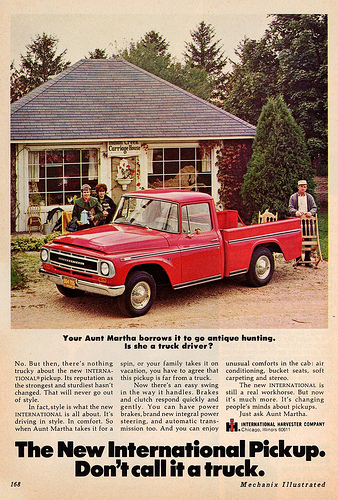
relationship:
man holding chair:
[288, 177, 319, 273] [295, 214, 325, 270]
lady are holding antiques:
[72, 183, 105, 233] [76, 202, 111, 227]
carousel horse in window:
[155, 166, 197, 191] [144, 144, 212, 198]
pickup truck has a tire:
[40, 185, 306, 317] [119, 269, 157, 320]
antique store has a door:
[9, 58, 262, 232] [110, 156, 137, 210]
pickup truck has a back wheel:
[40, 185, 306, 317] [247, 246, 274, 288]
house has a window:
[9, 58, 262, 232] [144, 144, 212, 198]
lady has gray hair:
[69, 180, 105, 233] [79, 179, 92, 193]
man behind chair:
[288, 177, 319, 273] [295, 214, 325, 270]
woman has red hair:
[93, 180, 118, 222] [94, 180, 109, 194]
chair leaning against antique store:
[27, 203, 44, 235] [9, 58, 262, 232]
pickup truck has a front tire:
[40, 185, 306, 317] [119, 269, 157, 320]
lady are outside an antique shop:
[72, 183, 105, 233] [9, 58, 262, 232]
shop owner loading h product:
[288, 177, 319, 273] [295, 214, 325, 270]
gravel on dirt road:
[11, 251, 326, 329] [10, 261, 330, 333]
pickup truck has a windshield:
[40, 185, 306, 317] [113, 195, 178, 235]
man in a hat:
[288, 177, 319, 273] [296, 174, 308, 186]